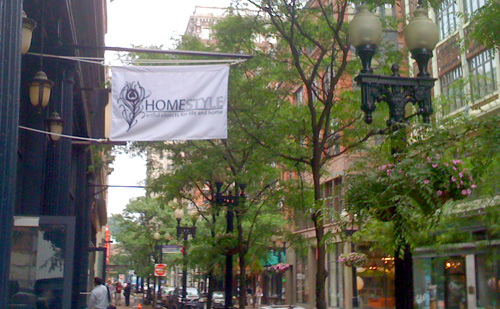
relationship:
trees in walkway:
[221, 32, 457, 277] [114, 207, 288, 303]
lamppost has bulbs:
[357, 56, 429, 305] [347, 5, 441, 67]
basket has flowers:
[330, 249, 369, 268] [348, 257, 356, 262]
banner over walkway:
[104, 63, 231, 146] [114, 207, 288, 303]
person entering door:
[86, 276, 112, 309] [81, 251, 106, 304]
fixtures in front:
[27, 71, 71, 147] [24, 49, 105, 297]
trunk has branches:
[305, 124, 332, 308] [254, 132, 377, 165]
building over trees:
[191, 5, 223, 37] [221, 32, 457, 277]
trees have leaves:
[221, 32, 457, 277] [242, 110, 286, 173]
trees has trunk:
[221, 32, 457, 277] [305, 124, 332, 308]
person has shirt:
[86, 276, 112, 309] [89, 286, 109, 309]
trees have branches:
[221, 32, 457, 277] [254, 132, 377, 165]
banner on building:
[104, 63, 231, 146] [2, 2, 107, 307]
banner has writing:
[104, 63, 231, 146] [146, 95, 223, 116]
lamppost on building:
[357, 56, 429, 305] [191, 5, 223, 37]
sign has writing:
[152, 262, 169, 277] [156, 265, 168, 276]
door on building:
[81, 251, 106, 304] [2, 2, 107, 307]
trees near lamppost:
[221, 32, 457, 277] [357, 56, 429, 305]